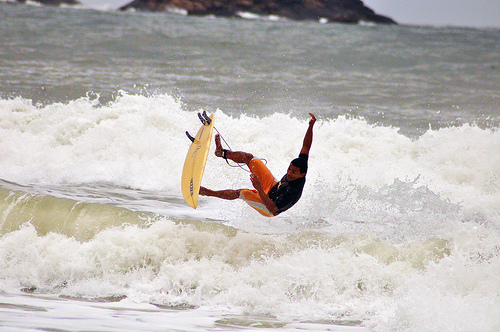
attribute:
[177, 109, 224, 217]
surfboard — yellow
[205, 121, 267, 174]
rope — anchored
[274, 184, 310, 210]
shirt — black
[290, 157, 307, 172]
hair — short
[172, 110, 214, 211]
hair — dark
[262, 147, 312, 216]
wet suit — black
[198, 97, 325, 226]
guy — midair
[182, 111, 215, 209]
surfboard — yellow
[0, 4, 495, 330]
water — grey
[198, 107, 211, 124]
fin — black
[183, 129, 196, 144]
fin — black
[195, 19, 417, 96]
sea — saltwater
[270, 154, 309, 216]
shirt — black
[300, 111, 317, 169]
arm — stretched out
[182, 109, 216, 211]
board — surf board